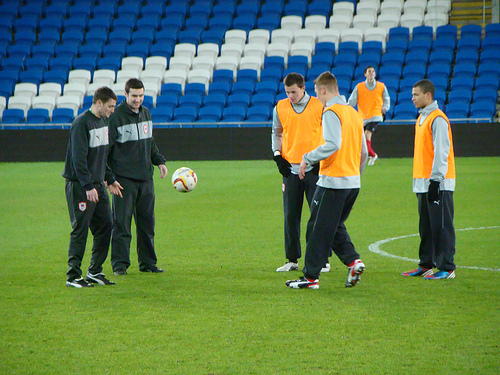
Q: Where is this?
A: This is at the field.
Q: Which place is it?
A: It is a field.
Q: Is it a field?
A: Yes, it is a field.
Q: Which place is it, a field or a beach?
A: It is a field.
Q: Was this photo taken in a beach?
A: No, the picture was taken in a field.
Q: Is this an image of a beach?
A: No, the picture is showing a field.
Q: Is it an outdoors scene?
A: Yes, it is outdoors.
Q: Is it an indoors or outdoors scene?
A: It is outdoors.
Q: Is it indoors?
A: No, it is outdoors.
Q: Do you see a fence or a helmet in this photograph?
A: No, there are no helmets or fences.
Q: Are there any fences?
A: No, there are no fences.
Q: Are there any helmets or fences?
A: No, there are no fences or helmets.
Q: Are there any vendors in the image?
A: No, there are no vendors.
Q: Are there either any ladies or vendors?
A: No, there are no vendors or ladies.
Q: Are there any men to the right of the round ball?
A: Yes, there is a man to the right of the ball.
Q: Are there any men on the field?
A: Yes, there is a man on the field.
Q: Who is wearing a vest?
A: The man is wearing a vest.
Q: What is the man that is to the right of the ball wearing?
A: The man is wearing a vest.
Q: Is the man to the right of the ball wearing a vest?
A: Yes, the man is wearing a vest.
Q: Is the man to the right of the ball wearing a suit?
A: No, the man is wearing a vest.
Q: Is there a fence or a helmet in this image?
A: No, there are no fences or helmets.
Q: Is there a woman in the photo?
A: No, there are no women.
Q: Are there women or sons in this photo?
A: No, there are no women or sons.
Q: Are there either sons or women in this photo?
A: No, there are no women or sons.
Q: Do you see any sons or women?
A: No, there are no women or sons.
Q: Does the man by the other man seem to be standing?
A: Yes, the man is standing.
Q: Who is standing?
A: The man is standing.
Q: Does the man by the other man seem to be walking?
A: No, the man is standing.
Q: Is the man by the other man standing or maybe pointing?
A: The man is standing.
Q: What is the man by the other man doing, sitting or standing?
A: The man is standing.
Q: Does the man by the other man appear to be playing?
A: Yes, the man is playing.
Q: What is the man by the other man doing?
A: The man is playing.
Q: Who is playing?
A: The man is playing.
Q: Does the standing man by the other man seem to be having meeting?
A: No, the man is playing.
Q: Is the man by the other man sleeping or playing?
A: The man is playing.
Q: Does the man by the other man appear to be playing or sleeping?
A: The man is playing.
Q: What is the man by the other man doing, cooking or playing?
A: The man is playing.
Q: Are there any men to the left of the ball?
A: Yes, there is a man to the left of the ball.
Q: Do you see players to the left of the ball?
A: No, there is a man to the left of the ball.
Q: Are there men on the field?
A: Yes, there is a man on the field.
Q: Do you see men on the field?
A: Yes, there is a man on the field.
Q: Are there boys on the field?
A: No, there is a man on the field.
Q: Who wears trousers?
A: The man wears trousers.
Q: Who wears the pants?
A: The man wears trousers.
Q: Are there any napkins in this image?
A: No, there are no napkins.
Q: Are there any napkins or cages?
A: No, there are no napkins or cages.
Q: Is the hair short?
A: Yes, the hair is short.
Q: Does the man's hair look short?
A: Yes, the hair is short.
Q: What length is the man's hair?
A: The hair is short.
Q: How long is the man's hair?
A: The hair is short.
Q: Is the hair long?
A: No, the hair is short.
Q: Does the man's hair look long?
A: No, the hair is short.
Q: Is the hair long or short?
A: The hair is short.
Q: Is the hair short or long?
A: The hair is short.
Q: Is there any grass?
A: Yes, there is grass.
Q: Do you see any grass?
A: Yes, there is grass.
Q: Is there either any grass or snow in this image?
A: Yes, there is grass.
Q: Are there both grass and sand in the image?
A: No, there is grass but no sand.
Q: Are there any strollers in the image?
A: No, there are no strollers.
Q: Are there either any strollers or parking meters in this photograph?
A: No, there are no strollers or parking meters.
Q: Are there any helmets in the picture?
A: No, there are no helmets.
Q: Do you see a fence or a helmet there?
A: No, there are no helmets or fences.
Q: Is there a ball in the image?
A: Yes, there is a ball.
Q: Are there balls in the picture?
A: Yes, there is a ball.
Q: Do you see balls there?
A: Yes, there is a ball.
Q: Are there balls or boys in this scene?
A: Yes, there is a ball.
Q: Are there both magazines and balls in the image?
A: No, there is a ball but no magazines.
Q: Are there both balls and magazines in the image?
A: No, there is a ball but no magazines.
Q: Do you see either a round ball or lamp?
A: Yes, there is a round ball.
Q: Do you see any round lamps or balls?
A: Yes, there is a round ball.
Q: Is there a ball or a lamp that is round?
A: Yes, the ball is round.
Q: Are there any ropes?
A: No, there are no ropes.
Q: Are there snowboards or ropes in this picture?
A: No, there are no ropes or snowboards.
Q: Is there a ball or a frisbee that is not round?
A: No, there is a ball but it is round.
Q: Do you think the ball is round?
A: Yes, the ball is round.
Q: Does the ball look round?
A: Yes, the ball is round.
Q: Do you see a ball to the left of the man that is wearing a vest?
A: Yes, there is a ball to the left of the man.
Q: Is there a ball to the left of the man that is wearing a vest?
A: Yes, there is a ball to the left of the man.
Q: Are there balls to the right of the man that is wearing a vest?
A: No, the ball is to the left of the man.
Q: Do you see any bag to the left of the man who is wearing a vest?
A: No, there is a ball to the left of the man.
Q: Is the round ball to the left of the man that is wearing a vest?
A: Yes, the ball is to the left of the man.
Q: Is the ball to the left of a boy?
A: No, the ball is to the left of the man.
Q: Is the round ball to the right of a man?
A: No, the ball is to the left of a man.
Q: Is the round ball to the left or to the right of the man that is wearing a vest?
A: The ball is to the left of the man.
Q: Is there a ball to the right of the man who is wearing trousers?
A: Yes, there is a ball to the right of the man.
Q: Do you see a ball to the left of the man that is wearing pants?
A: No, the ball is to the right of the man.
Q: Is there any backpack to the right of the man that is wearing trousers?
A: No, there is a ball to the right of the man.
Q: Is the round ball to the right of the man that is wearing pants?
A: Yes, the ball is to the right of the man.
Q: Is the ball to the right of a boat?
A: No, the ball is to the right of the man.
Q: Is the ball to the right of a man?
A: Yes, the ball is to the right of a man.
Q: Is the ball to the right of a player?
A: No, the ball is to the right of a man.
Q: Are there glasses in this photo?
A: No, there are no glasses.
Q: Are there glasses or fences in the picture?
A: No, there are no glasses or fences.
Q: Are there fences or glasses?
A: No, there are no glasses or fences.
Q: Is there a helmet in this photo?
A: No, there are no helmets.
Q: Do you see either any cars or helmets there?
A: No, there are no helmets or cars.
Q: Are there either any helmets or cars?
A: No, there are no helmets or cars.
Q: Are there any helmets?
A: No, there are no helmets.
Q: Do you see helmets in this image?
A: No, there are no helmets.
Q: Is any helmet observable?
A: No, there are no helmets.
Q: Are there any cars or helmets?
A: No, there are no helmets or cars.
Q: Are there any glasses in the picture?
A: No, there are no glasses.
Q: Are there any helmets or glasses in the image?
A: No, there are no glasses or helmets.